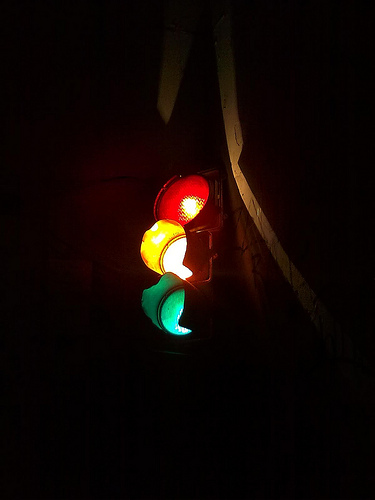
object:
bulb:
[182, 197, 199, 216]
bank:
[137, 165, 211, 340]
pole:
[217, 25, 332, 339]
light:
[152, 169, 215, 228]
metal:
[238, 230, 263, 270]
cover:
[149, 235, 160, 250]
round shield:
[140, 271, 193, 339]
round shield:
[139, 217, 193, 279]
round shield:
[154, 173, 211, 226]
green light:
[139, 272, 192, 337]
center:
[182, 197, 200, 217]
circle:
[157, 283, 192, 337]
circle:
[159, 234, 193, 281]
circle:
[156, 173, 209, 227]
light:
[139, 217, 193, 280]